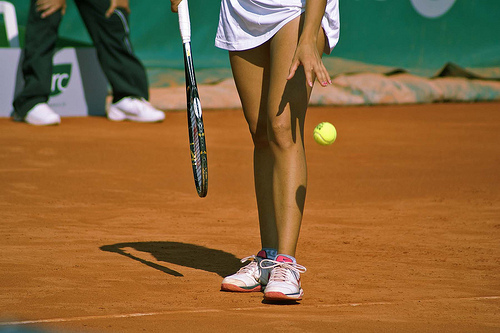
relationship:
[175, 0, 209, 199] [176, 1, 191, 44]
racket has handle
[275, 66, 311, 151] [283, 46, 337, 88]
shadow of hands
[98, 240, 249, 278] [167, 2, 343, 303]
shadow cast by player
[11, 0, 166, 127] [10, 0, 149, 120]
man wearing pants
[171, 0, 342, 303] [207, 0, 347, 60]
player wearing skirt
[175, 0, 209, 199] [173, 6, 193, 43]
racket with handle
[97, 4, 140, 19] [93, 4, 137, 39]
hand on knee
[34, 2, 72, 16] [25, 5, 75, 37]
hand on knee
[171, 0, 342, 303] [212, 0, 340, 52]
player wearing skirt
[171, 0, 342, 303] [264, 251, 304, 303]
player wearing tennis shoe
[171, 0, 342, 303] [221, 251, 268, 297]
player wearing tennis shoe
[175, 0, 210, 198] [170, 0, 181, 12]
racket in hand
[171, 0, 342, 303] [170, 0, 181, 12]
player has hand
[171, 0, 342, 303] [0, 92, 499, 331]
player on court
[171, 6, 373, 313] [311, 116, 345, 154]
player ready to serve ball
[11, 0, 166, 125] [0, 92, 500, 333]
man standing behind court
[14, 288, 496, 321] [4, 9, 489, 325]
markings in photo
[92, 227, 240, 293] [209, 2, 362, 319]
shadow of a woman